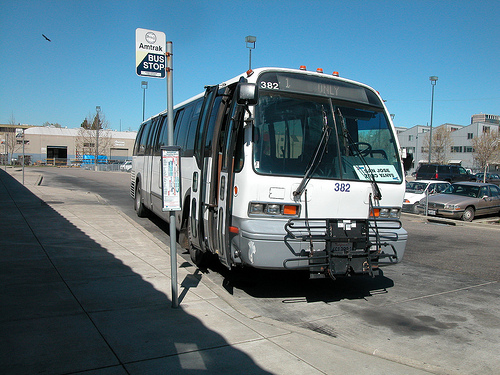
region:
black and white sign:
[118, 22, 180, 84]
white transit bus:
[114, 59, 429, 267]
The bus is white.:
[108, 60, 423, 319]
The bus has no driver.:
[113, 48, 414, 323]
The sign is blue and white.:
[131, 20, 172, 84]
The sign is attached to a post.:
[119, 19, 202, 314]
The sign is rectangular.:
[126, 21, 171, 83]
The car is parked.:
[416, 169, 499, 235]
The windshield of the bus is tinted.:
[243, 85, 409, 191]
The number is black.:
[331, 177, 341, 194]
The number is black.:
[343, 178, 353, 199]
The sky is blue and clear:
[0, 1, 496, 129]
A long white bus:
[125, 60, 406, 282]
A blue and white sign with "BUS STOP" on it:
[130, 22, 167, 77]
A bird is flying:
[35, 26, 52, 46]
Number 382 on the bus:
[330, 175, 351, 192]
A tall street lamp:
[421, 70, 437, 160]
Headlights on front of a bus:
[242, 195, 399, 220]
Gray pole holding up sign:
[130, 21, 186, 306]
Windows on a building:
[445, 127, 480, 157]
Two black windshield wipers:
[290, 120, 386, 203]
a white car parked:
[401, 172, 445, 222]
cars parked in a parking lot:
[404, 145, 498, 252]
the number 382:
[311, 161, 368, 207]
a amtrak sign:
[131, 28, 194, 114]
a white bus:
[80, 63, 440, 372]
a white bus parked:
[104, 32, 425, 323]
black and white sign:
[128, 28, 169, 82]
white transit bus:
[187, 12, 399, 284]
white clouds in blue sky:
[398, 42, 420, 60]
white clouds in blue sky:
[75, 22, 123, 62]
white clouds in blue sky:
[47, 59, 94, 97]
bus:
[95, 82, 383, 264]